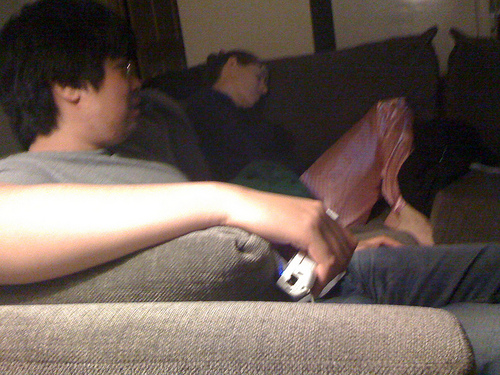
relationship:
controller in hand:
[276, 206, 347, 301] [230, 183, 356, 295]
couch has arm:
[8, 25, 489, 373] [0, 294, 485, 371]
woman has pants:
[187, 45, 435, 244] [301, 95, 408, 218]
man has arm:
[4, 3, 499, 369] [17, 180, 351, 292]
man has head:
[0, 0, 500, 374] [7, 8, 143, 153]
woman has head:
[187, 45, 435, 244] [201, 46, 271, 113]